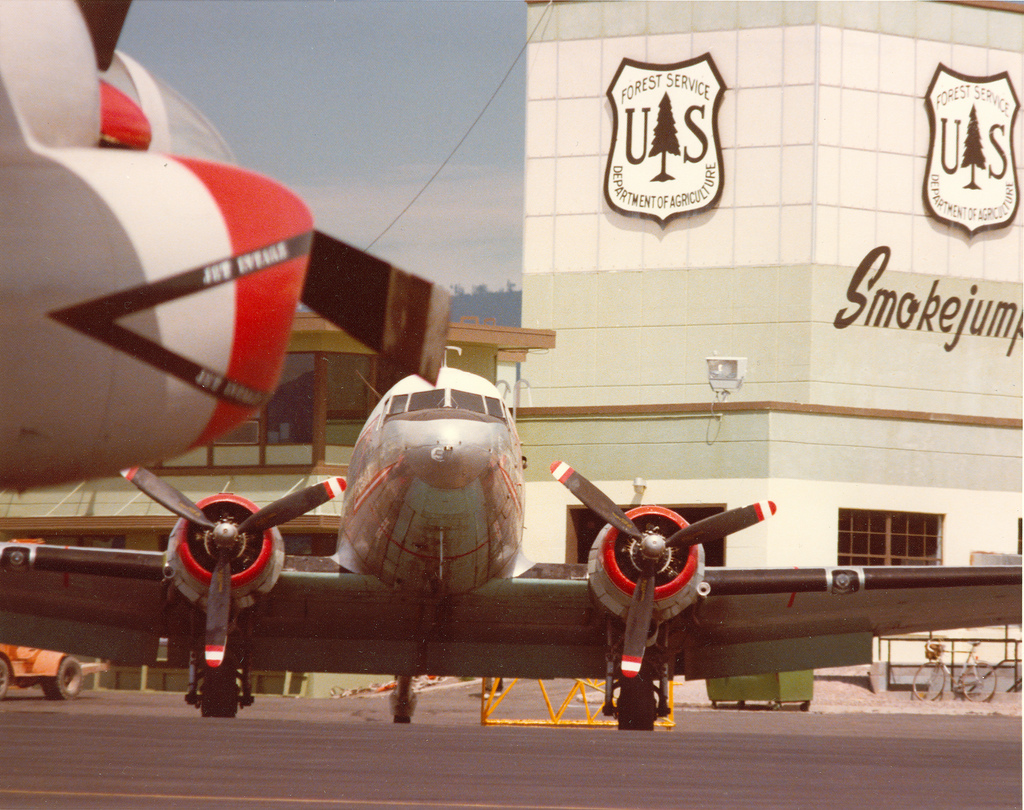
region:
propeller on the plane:
[149, 459, 187, 514]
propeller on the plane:
[194, 584, 255, 661]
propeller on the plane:
[576, 462, 619, 516]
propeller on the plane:
[716, 508, 783, 537]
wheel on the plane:
[178, 695, 229, 721]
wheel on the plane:
[610, 695, 652, 734]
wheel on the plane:
[74, 660, 93, 706]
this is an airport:
[61, 57, 962, 724]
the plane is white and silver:
[275, 353, 813, 759]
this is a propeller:
[482, 417, 812, 715]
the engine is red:
[550, 502, 827, 709]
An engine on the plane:
[548, 447, 787, 685]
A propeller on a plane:
[545, 450, 793, 681]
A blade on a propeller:
[199, 554, 241, 676]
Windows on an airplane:
[387, 379, 506, 427]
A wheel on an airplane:
[189, 648, 250, 713]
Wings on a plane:
[9, 535, 1021, 666]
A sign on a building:
[597, 47, 730, 228]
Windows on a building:
[828, 500, 955, 567]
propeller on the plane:
[162, 594, 245, 667]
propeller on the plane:
[596, 603, 683, 665]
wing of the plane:
[823, 565, 959, 627]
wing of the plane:
[7, 543, 122, 594]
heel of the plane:
[165, 679, 251, 717]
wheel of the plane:
[604, 698, 661, 724]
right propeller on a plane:
[40, 451, 358, 699]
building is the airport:
[8, 14, 1021, 708]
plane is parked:
[5, 367, 1001, 732]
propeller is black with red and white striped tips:
[557, 441, 782, 677]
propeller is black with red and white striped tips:
[114, 459, 345, 676]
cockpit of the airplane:
[327, 364, 549, 599]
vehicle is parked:
[0, 644, 93, 692]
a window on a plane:
[388, 386, 407, 419]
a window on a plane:
[408, 389, 441, 412]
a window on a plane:
[448, 384, 484, 423]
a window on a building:
[846, 510, 892, 575]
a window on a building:
[675, 506, 730, 568]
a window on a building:
[285, 528, 336, 552]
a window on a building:
[255, 351, 309, 447]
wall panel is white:
[741, 147, 784, 205]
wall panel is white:
[688, 205, 736, 269]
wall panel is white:
[777, 204, 815, 265]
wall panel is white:
[820, 204, 839, 258]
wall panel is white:
[842, 208, 874, 262]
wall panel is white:
[912, 217, 939, 271]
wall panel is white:
[979, 221, 1021, 278]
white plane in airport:
[131, 347, 926, 759]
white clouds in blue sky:
[160, 22, 236, 95]